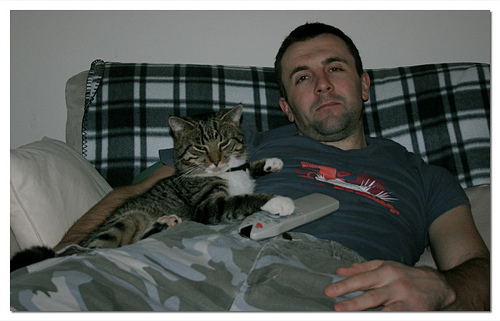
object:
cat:
[11, 102, 296, 273]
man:
[9, 22, 491, 312]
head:
[273, 22, 371, 138]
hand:
[323, 259, 450, 311]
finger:
[336, 260, 381, 275]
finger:
[324, 271, 381, 298]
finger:
[333, 290, 391, 311]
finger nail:
[324, 283, 340, 295]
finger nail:
[335, 302, 349, 312]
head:
[168, 104, 247, 176]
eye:
[194, 142, 209, 152]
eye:
[220, 139, 231, 148]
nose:
[209, 156, 221, 165]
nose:
[314, 72, 335, 96]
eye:
[295, 73, 312, 86]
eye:
[327, 65, 345, 75]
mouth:
[314, 100, 343, 111]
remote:
[239, 192, 340, 242]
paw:
[262, 192, 296, 217]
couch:
[10, 63, 491, 268]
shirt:
[159, 123, 471, 265]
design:
[294, 159, 400, 216]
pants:
[9, 220, 382, 312]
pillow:
[10, 135, 112, 249]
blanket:
[82, 59, 492, 196]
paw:
[262, 157, 284, 174]